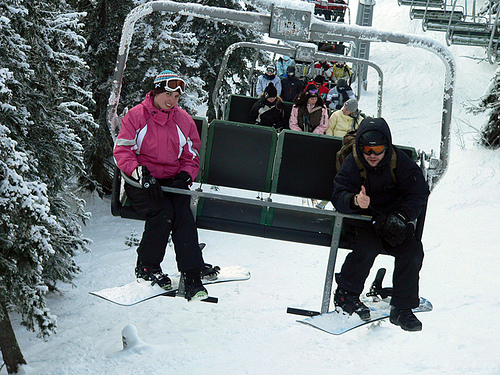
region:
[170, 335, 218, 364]
a snowy surface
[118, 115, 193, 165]
a lady with pink and white shirt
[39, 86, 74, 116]
snow on the leaves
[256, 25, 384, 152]
passengers on the trail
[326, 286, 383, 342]
a man with black shoes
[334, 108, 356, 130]
a lady with yellow jacket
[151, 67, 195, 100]
a lady with white eye glass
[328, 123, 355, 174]
a brown hand bag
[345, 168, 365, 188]
a black jacket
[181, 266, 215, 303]
a lady with black and green shoes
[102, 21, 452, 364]
people on a chairlift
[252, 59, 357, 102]
four people on a chairlift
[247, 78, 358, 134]
three people on a chairlift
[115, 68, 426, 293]
two people on a chairlift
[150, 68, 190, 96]
goggles on a hat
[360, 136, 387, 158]
a person wearing goggles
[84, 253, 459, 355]
people wearing snowboards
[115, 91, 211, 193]
a girl in a pink jacket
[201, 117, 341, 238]
empty seats on a chairlift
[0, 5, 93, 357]
snow on the trees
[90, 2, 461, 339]
Many people riding a ski lift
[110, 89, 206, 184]
A pink and white jacket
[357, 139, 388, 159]
A pair of goggles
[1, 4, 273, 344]
The pine trees are snow covered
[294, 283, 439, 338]
A snowboard under the feet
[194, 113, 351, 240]
Two empty black seats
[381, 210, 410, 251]
The glove is black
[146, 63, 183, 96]
The hat is colorful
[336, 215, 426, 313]
A pair of black pants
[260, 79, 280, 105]
Black hat on person's head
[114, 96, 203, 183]
a pink and white jacket on a woman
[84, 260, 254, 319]
a snowboard on a woman's feet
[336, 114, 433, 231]
a black coat on a person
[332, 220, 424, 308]
black pants on a person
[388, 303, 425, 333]
a black snow boot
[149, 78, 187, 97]
ski goggles on a woman's head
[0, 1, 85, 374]
a green pine tree next to a ski lift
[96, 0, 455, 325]
a ski lift carrying people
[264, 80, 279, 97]
a black hat on a person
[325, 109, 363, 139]
a yellow coat on a person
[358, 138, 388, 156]
ski goggles on a person's face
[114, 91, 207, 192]
a pink and white coat on a woman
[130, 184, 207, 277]
black pants on a woman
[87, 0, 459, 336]
a ski lift carrying two people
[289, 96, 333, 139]
a pink and brown coat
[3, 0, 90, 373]
a snow covered pine tree near a ski lift